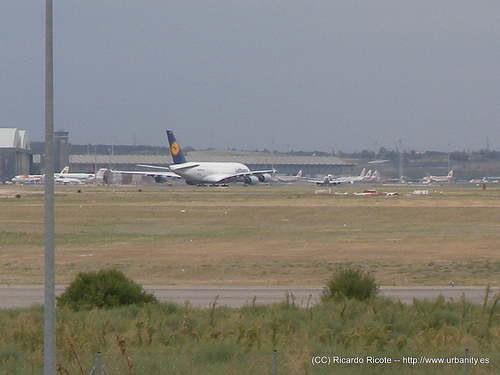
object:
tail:
[164, 129, 187, 166]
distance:
[2, 1, 483, 178]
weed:
[115, 334, 130, 354]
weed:
[122, 334, 349, 373]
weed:
[62, 332, 85, 372]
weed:
[52, 360, 69, 372]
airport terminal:
[33, 148, 359, 170]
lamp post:
[41, 0, 58, 372]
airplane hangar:
[2, 126, 22, 182]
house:
[420, 149, 428, 153]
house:
[414, 150, 420, 154]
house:
[468, 152, 484, 161]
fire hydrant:
[481, 180, 484, 188]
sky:
[2, 1, 483, 153]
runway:
[91, 270, 493, 298]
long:
[3, 250, 493, 309]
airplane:
[122, 133, 285, 190]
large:
[52, 116, 73, 170]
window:
[18, 172, 36, 181]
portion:
[6, 117, 90, 201]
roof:
[17, 149, 333, 167]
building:
[52, 150, 417, 167]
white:
[107, 160, 176, 182]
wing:
[104, 169, 177, 177]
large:
[364, 183, 403, 205]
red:
[318, 184, 414, 205]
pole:
[32, 11, 79, 375]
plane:
[104, 124, 306, 225]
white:
[109, 146, 282, 192]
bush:
[58, 255, 156, 314]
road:
[4, 266, 478, 315]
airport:
[41, 178, 492, 338]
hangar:
[3, 98, 341, 174]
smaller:
[4, 163, 152, 253]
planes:
[7, 121, 175, 291]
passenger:
[57, 165, 471, 298]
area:
[64, 167, 437, 301]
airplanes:
[272, 134, 467, 224]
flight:
[300, 111, 456, 198]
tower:
[381, 100, 414, 174]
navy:
[137, 108, 219, 243]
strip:
[32, 261, 432, 374]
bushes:
[74, 290, 498, 375]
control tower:
[50, 129, 66, 178]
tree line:
[55, 144, 470, 163]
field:
[10, 193, 462, 283]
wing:
[205, 169, 278, 182]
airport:
[3, 206, 483, 284]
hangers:
[0, 128, 33, 181]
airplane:
[422, 163, 455, 189]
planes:
[271, 167, 463, 190]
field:
[38, 182, 478, 275]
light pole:
[38, 3, 60, 373]